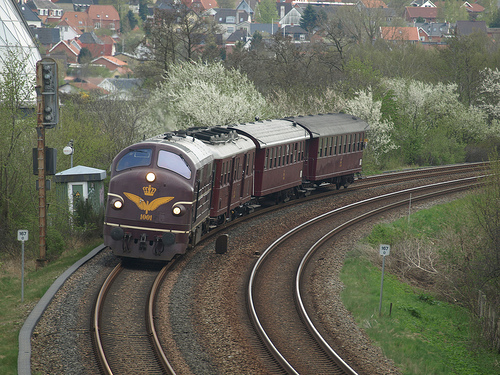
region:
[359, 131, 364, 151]
glass window on train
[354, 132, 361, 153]
glass window on train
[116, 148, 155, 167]
glass window on train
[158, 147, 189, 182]
glass window on train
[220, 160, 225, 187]
glass window on train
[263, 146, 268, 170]
glass window on train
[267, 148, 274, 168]
glass window on train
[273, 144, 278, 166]
glass window on train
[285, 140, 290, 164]
glass window on train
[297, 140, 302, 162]
glass window on train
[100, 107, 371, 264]
A train with three cars and an engine traveling down the tracks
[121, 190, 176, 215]
Picture of a golden bird on the front of a train engine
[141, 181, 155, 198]
Picture of a golden crown on the front of a train engine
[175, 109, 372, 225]
Three maroon colored passenger cars of a train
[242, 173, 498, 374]
Silver train tracks that are curved inward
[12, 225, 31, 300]
Small white sign on a pole next to train tracks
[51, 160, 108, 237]
Tiny green building next to a set of train tracks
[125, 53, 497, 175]
Trees that have white blossoms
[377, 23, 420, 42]
Red rooftop of a small house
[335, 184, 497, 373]
Fresh green grass next to train tracks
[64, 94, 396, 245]
this is a train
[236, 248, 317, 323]
this is a railway line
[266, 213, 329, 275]
this is a railway line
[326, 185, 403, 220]
this is a railway line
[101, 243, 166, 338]
this is a railway line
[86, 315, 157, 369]
this is a railway line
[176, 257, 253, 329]
this is a railway line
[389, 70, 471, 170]
this is a bushy tree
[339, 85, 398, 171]
this is a bushy tree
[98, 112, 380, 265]
a brown train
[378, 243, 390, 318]
a white street sign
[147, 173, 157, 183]
a headlight on the train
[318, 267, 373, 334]
rocks next to the train tracks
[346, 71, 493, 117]
trees behind the train tracks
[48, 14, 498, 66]
houses in the background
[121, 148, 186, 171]
the windshield of the train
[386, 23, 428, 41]
a red roof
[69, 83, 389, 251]
brown train on the tracks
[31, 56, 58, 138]
signal on a pole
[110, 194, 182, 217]
head lights on a train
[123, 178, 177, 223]
eagle on a train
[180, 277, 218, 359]
gravel between tracks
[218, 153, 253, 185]
windows on a train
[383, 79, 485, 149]
leaves on a tree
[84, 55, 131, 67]
orange roof on a house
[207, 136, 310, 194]
red train car